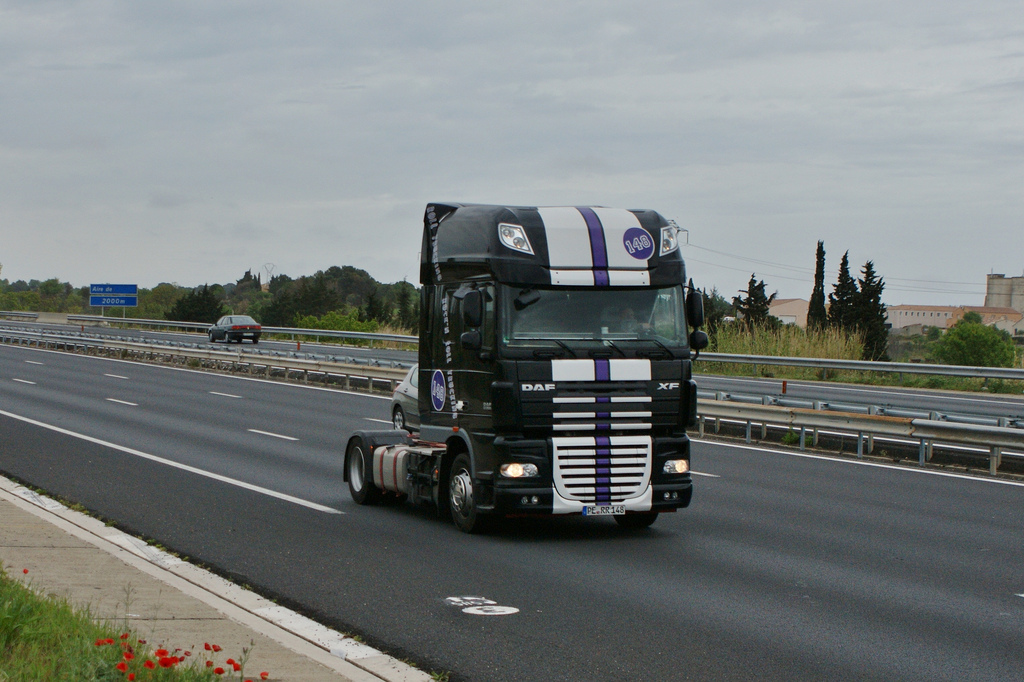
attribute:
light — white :
[673, 462, 689, 478]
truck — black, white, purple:
[365, 181, 752, 564]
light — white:
[481, 449, 536, 499]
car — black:
[192, 315, 266, 341]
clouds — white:
[192, 56, 264, 121]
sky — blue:
[654, 40, 853, 188]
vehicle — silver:
[378, 351, 418, 421]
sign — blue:
[92, 272, 144, 311]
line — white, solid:
[69, 425, 214, 493]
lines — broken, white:
[103, 384, 296, 434]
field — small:
[727, 272, 916, 366]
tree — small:
[721, 259, 788, 348]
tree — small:
[829, 262, 933, 379]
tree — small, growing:
[148, 279, 254, 340]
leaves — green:
[827, 268, 884, 348]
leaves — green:
[829, 264, 955, 385]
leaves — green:
[779, 242, 879, 370]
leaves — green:
[701, 264, 801, 317]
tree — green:
[256, 258, 382, 325]